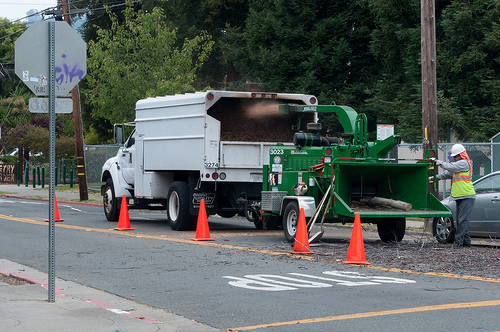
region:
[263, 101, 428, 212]
Green chipper trailer on back of truck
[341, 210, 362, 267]
Orange traffic cone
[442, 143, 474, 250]
City employee working chipper truck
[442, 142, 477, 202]
City employee wearing safety vest and hard hat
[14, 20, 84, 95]
Purple graffiti on back of stop sign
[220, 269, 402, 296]
"STOP" in white lettering on road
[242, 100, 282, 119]
Chips of wood flying into chipper truck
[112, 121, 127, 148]
Side mirror on chipper truck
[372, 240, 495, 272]
Dry, broken twigs laying on street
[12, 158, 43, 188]
Green posts sticking out of ground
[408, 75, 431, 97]
The Light pole on the side of the rode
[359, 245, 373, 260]
A orange cone on the ground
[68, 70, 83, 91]
A stop sign someone drew on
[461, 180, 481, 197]
A man wearing bright yellow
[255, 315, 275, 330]
A yellow line on the ground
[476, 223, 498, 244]
A grey car on the raod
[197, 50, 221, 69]
The green leaves on the tree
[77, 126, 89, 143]
A light pole underground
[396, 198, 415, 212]
A limb in the back of a lifter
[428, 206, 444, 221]
A green lifter with limbs in back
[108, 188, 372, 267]
line of traffic cones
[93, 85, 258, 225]
large white work truck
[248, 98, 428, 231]
green wood chipper working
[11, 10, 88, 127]
back of stop sign with graffiti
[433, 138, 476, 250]
man wearing reflective clothing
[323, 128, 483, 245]
man working wood chipper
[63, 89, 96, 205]
leaning telephone pole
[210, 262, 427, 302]
"stop" word on road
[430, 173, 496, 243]
front of silver car behind man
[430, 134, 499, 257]
man in front of silver car working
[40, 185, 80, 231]
the cone is orange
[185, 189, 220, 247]
the cone is orange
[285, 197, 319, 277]
the cone is orange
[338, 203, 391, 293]
the cone is orange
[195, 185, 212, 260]
the cone is orange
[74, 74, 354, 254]
the truck is white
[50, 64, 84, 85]
purple graffitti on the back of street sign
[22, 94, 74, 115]
the back of a rectangular streets sign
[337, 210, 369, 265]
orange cone on the street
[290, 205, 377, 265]
two orange cones on a street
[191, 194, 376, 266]
three orange cones on a street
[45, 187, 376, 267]
line of orange cones on the street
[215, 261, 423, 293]
bold white text on a street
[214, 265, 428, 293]
white bold text on a street reading STOP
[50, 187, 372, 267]
five orange cones on a street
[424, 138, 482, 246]
a street worker